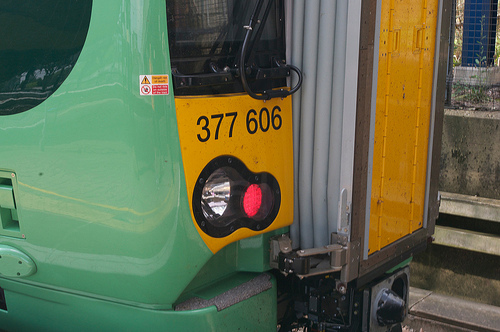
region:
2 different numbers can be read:
[198, 90, 286, 140]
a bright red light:
[200, 170, 294, 234]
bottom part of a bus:
[278, 246, 425, 323]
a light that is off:
[192, 158, 247, 249]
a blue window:
[461, 11, 489, 82]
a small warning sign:
[121, 63, 185, 115]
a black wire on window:
[216, 18, 303, 98]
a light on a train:
[186, 161, 284, 242]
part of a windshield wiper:
[180, 1, 292, 88]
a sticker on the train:
[137, 72, 169, 96]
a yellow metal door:
[365, 0, 443, 252]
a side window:
[2, 2, 84, 114]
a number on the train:
[186, 96, 291, 151]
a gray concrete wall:
[444, 102, 499, 190]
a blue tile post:
[460, 1, 492, 61]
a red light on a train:
[243, 181, 288, 221]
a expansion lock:
[270, 236, 345, 285]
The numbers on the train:
[185, 103, 293, 147]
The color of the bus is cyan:
[57, 180, 149, 280]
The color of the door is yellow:
[389, 11, 416, 221]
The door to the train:
[356, 0, 447, 260]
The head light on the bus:
[191, 156, 294, 229]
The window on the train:
[166, 0, 289, 51]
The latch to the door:
[257, 225, 364, 287]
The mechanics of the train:
[273, 268, 415, 330]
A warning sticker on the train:
[134, 70, 171, 99]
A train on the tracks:
[1, 3, 493, 326]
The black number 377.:
[192, 110, 237, 140]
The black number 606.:
[242, 105, 282, 134]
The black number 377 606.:
[194, 102, 282, 141]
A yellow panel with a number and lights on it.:
[171, 85, 291, 250]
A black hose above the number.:
[240, 0, 300, 100]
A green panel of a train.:
[0, 0, 290, 330]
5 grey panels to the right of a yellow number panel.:
[281, 1, 353, 236]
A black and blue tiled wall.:
[462, 2, 498, 65]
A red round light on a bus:
[242, 183, 262, 217]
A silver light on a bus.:
[198, 169, 230, 222]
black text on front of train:
[189, 104, 291, 152]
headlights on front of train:
[183, 159, 293, 239]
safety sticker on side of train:
[122, 57, 175, 108]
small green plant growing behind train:
[467, 17, 492, 111]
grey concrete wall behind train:
[444, 112, 497, 198]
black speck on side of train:
[25, 161, 58, 194]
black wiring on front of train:
[236, 17, 309, 102]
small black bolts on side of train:
[11, 257, 23, 279]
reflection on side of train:
[49, 137, 164, 279]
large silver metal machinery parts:
[261, 231, 350, 277]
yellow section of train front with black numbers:
[171, 85, 303, 250]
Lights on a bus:
[188, 154, 278, 234]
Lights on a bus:
[191, 160, 276, 230]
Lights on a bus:
[186, 148, 288, 242]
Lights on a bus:
[178, 147, 288, 246]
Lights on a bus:
[192, 150, 287, 235]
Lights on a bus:
[193, 156, 274, 237]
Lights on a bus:
[196, 163, 269, 225]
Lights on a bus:
[196, 158, 275, 229]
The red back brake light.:
[241, 177, 268, 232]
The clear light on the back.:
[196, 160, 234, 218]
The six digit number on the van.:
[187, 108, 289, 138]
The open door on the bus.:
[291, 3, 436, 275]